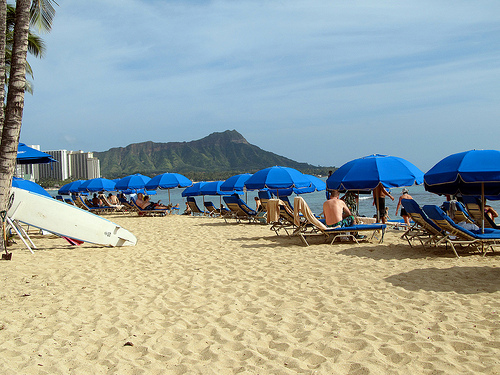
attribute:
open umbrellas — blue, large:
[187, 144, 499, 249]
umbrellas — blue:
[10, 139, 497, 203]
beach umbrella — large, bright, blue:
[182, 180, 209, 195]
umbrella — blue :
[425, 149, 498, 199]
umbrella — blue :
[326, 152, 423, 190]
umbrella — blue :
[245, 164, 308, 190]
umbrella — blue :
[145, 170, 191, 188]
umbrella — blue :
[78, 178, 114, 190]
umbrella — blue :
[246, 162, 313, 186]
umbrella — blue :
[220, 171, 252, 193]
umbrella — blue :
[269, 169, 324, 194]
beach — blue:
[3, 205, 497, 373]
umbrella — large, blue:
[145, 169, 191, 191]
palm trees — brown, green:
[0, 4, 64, 146]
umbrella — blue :
[58, 178, 84, 194]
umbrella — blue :
[422, 147, 487, 200]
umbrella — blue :
[219, 172, 249, 188]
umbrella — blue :
[327, 153, 427, 186]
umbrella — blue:
[427, 142, 497, 204]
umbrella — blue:
[244, 160, 309, 187]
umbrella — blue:
[271, 173, 333, 194]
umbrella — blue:
[223, 172, 258, 192]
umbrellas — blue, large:
[50, 159, 496, 209]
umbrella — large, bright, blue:
[325, 149, 428, 196]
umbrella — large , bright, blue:
[327, 156, 429, 193]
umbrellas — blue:
[51, 160, 492, 204]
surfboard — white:
[9, 171, 138, 256]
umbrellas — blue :
[321, 142, 498, 261]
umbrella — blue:
[182, 181, 212, 216]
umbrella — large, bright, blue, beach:
[143, 168, 195, 215]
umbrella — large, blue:
[146, 171, 193, 211]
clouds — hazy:
[117, 51, 213, 92]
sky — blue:
[279, 3, 491, 86]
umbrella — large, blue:
[228, 161, 356, 234]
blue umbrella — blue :
[422, 145, 497, 182]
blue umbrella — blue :
[334, 153, 419, 193]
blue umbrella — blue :
[247, 166, 316, 196]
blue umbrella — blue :
[157, 169, 196, 193]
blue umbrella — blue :
[63, 174, 141, 195]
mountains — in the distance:
[91, 127, 339, 182]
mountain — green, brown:
[105, 124, 331, 169]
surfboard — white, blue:
[8, 182, 138, 250]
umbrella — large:
[144, 169, 193, 189]